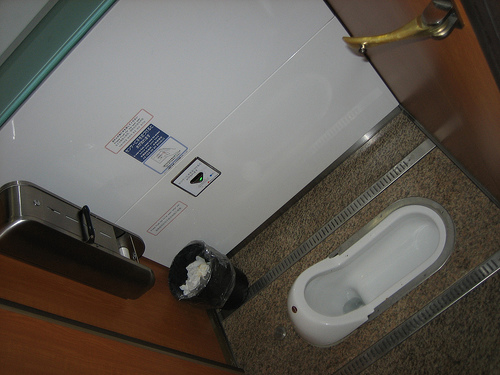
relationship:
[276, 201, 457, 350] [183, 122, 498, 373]
toilet in floor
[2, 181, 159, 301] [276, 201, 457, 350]
toilet paper holder near toilet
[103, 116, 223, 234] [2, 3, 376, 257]
signs hanging on wall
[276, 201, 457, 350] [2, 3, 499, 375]
toilet in bathroom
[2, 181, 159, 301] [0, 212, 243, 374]
toilet paper holder attached to wall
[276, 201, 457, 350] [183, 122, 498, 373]
toilet on floor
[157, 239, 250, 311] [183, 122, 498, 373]
trash can on floor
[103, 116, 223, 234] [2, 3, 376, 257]
signs on wall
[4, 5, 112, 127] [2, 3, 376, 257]
beam on wall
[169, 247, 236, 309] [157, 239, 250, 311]
plastic bag in trash can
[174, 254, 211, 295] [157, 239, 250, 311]
garbage in trash can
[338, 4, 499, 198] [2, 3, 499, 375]
door to bathroom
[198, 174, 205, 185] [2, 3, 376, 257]
light on wall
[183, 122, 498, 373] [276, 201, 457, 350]
floor near toilet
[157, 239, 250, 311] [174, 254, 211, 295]
trash can filled with garbage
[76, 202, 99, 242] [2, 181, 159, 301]
lever on toilet paper holder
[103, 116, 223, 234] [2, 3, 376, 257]
signs posted on wall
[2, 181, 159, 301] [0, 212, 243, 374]
toilet paper holder on wall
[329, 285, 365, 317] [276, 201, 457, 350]
water in toilet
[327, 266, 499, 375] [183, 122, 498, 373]
track on floor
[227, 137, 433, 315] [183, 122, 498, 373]
track on floor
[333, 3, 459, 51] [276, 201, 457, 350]
wall mount hook near toilet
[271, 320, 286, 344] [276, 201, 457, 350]
flush button next to toilet